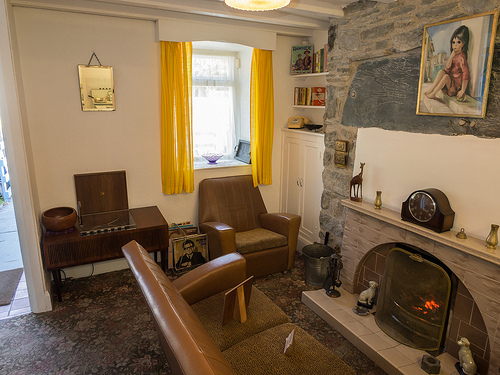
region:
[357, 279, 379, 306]
the statue of a dog next to the fireplace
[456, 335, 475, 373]
the statue of a dog next to the fireplace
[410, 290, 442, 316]
the fire in the fireplace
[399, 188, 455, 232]
the clock on the mantle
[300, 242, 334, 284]
the metal basket near the fireplace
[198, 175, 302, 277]
the brown chair under the window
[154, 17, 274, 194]
the window in the room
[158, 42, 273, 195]
the yellow curtains on the window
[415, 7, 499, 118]
the picture hanging above the fireplace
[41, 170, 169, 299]
the old record player along the wall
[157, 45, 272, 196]
orange curtains near the window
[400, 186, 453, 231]
clock above the fire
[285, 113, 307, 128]
telephone on the shelf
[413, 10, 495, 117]
picture frame of kid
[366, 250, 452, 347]
fire place in use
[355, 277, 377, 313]
cat statue near the fire place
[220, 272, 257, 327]
picture frame on the sofa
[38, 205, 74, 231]
bowl on side table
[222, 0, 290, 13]
ceiling lamp up above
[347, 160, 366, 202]
statue of giraffe on ledge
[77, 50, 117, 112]
frameless rectangular mirror hung on cord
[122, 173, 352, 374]
matching brown couch and armchair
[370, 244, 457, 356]
metal screen in front of fireplace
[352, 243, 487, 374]
two small ceramic dogs on either side of fireplace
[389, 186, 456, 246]
round faced clock on mantle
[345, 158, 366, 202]
figurine of giraffe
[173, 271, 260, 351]
frame on couch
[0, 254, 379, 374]
dark floral print carpet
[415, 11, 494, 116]
painting of a young girl sitting near a wall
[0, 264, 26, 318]
brown mat outside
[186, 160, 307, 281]
chair sitting under the window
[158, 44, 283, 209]
bright yellow curtains on the window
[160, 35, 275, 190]
curtains are pushed back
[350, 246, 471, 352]
orange fire in the fireplace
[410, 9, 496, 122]
painting hanging on the wall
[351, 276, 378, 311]
animal figurine on the fireplace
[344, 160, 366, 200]
giraffe figurine on the mantle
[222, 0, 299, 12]
light fixture on the ceiling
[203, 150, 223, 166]
bowl on the window ledge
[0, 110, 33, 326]
door is open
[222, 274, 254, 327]
a picture frame sitting on couch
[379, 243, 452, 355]
a metal fireplace guard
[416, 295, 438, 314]
ember of a fireplace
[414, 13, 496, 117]
a large painting with gold frame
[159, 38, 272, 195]
a set of yellow curtains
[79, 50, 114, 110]
a plaque hanging by a string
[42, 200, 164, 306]
dark brown wooden desk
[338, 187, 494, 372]
a mantle above a fireplace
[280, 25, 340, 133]
an inset bookshelf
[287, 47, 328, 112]
books on bookshelf